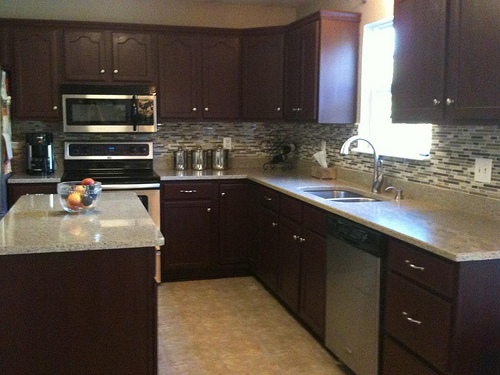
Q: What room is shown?
A: Kitchen.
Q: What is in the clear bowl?
A: Fruit.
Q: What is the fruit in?
A: Bowl.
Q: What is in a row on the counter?
A: Canisters.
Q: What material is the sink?
A: Stainless.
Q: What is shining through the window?
A: Sun.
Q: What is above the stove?
A: Microwave.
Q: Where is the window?
A: Between two cupboards.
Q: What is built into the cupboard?
A: A dishwasher.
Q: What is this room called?
A: Kitchen.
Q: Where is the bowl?
A: On the counter.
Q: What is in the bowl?
A: Fruit.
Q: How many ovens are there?
A: One.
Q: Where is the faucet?
A: Above the sink.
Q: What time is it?
A: Daytime.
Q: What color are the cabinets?
A: Brown.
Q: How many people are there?
A: None.